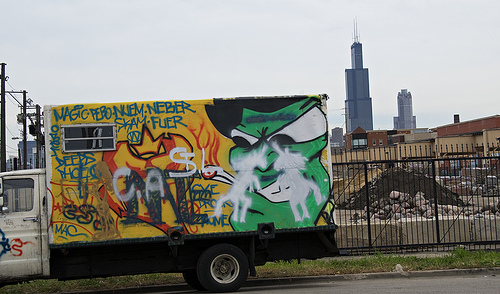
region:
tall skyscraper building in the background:
[341, 12, 368, 141]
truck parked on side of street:
[5, 77, 352, 288]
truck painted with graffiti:
[87, 108, 314, 225]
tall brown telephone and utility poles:
[0, 57, 48, 169]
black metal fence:
[328, 133, 498, 253]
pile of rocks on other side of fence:
[364, 182, 454, 226]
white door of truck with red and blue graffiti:
[0, 169, 54, 258]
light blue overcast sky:
[77, 12, 312, 87]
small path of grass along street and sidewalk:
[319, 245, 494, 273]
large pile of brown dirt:
[347, 155, 473, 212]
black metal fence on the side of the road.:
[337, 149, 479, 262]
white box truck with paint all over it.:
[0, 87, 337, 277]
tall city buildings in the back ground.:
[321, 24, 427, 148]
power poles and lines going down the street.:
[1, 54, 67, 179]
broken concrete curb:
[258, 244, 467, 291]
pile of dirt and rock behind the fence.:
[348, 149, 495, 239]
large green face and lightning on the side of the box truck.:
[198, 95, 362, 260]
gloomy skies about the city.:
[26, 10, 491, 100]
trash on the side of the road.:
[372, 258, 427, 280]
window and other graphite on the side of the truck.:
[43, 110, 225, 241]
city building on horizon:
[340, 27, 379, 143]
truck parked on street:
[5, 97, 347, 282]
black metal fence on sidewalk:
[351, 146, 465, 240]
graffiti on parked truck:
[133, 124, 229, 221]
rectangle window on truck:
[53, 114, 123, 159]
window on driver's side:
[7, 168, 42, 218]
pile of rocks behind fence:
[362, 190, 452, 224]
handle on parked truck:
[17, 212, 44, 227]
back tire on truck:
[188, 241, 259, 291]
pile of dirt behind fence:
[344, 157, 469, 216]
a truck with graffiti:
[0, 86, 345, 286]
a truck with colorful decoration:
[0, 90, 338, 290]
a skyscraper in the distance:
[342, 17, 374, 143]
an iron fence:
[347, 136, 491, 247]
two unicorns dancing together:
[205, 136, 322, 227]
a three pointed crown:
[118, 117, 169, 167]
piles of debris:
[335, 160, 474, 227]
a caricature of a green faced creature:
[205, 98, 336, 228]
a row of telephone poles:
[0, 54, 40, 170]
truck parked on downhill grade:
[0, 82, 350, 292]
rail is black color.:
[350, 152, 476, 238]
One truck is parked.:
[10, 110, 295, 275]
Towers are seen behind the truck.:
[335, 46, 415, 126]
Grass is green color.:
[350, 255, 375, 261]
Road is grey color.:
[390, 275, 495, 287]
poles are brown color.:
[0, 61, 45, 157]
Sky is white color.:
[30, 15, 235, 66]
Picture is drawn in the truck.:
[55, 112, 316, 223]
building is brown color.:
[353, 125, 496, 170]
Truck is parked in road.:
[161, 198, 381, 293]